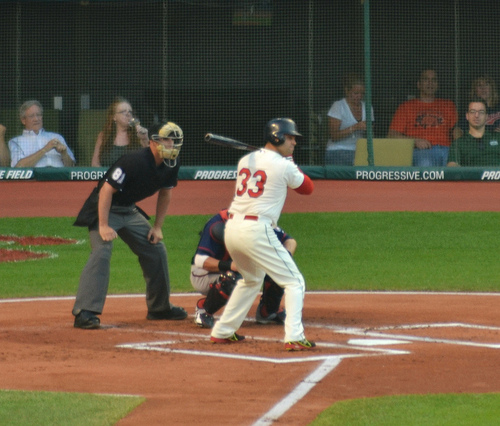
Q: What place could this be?
A: It is a field.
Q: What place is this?
A: It is a field.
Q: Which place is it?
A: It is a field.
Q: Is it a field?
A: Yes, it is a field.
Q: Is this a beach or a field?
A: It is a field.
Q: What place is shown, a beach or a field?
A: It is a field.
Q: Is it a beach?
A: No, it is a field.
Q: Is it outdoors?
A: Yes, it is outdoors.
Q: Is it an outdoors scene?
A: Yes, it is outdoors.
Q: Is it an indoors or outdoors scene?
A: It is outdoors.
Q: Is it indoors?
A: No, it is outdoors.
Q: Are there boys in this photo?
A: No, there are no boys.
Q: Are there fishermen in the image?
A: No, there are no fishermen.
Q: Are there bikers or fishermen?
A: No, there are no fishermen or bikers.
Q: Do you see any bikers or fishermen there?
A: No, there are no fishermen or bikers.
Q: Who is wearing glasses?
A: The man is wearing glasses.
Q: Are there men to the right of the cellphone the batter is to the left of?
A: Yes, there is a man to the right of the cellphone.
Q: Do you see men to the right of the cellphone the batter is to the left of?
A: Yes, there is a man to the right of the cellphone.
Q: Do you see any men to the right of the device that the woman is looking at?
A: Yes, there is a man to the right of the cellphone.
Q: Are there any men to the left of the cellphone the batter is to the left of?
A: No, the man is to the right of the mobile phone.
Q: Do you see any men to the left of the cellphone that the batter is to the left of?
A: No, the man is to the right of the mobile phone.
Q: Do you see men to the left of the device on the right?
A: No, the man is to the right of the mobile phone.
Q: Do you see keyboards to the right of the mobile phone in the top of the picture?
A: No, there is a man to the right of the cellphone.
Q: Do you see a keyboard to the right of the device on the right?
A: No, there is a man to the right of the cellphone.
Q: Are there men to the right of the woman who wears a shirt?
A: Yes, there is a man to the right of the woman.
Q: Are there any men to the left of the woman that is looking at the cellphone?
A: No, the man is to the right of the woman.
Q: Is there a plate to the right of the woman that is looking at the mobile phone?
A: No, there is a man to the right of the woman.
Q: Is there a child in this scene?
A: No, there are no children.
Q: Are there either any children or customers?
A: No, there are no children or customers.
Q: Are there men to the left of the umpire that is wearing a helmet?
A: Yes, there is a man to the left of the umpire.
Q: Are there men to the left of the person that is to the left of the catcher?
A: Yes, there is a man to the left of the umpire.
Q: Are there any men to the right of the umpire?
A: No, the man is to the left of the umpire.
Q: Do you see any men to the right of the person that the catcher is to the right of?
A: No, the man is to the left of the umpire.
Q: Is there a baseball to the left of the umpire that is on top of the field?
A: No, there is a man to the left of the umpire.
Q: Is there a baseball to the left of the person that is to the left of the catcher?
A: No, there is a man to the left of the umpire.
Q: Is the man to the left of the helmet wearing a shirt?
A: Yes, the man is wearing a shirt.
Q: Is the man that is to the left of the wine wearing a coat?
A: No, the man is wearing a shirt.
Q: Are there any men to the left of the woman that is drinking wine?
A: Yes, there is a man to the left of the woman.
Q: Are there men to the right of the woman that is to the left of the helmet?
A: No, the man is to the left of the woman.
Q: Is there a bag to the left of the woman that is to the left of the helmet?
A: No, there is a man to the left of the woman.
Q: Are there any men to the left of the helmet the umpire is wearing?
A: Yes, there is a man to the left of the helmet.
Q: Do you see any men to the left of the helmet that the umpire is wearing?
A: Yes, there is a man to the left of the helmet.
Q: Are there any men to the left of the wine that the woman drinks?
A: Yes, there is a man to the left of the wine.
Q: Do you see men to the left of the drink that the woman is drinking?
A: Yes, there is a man to the left of the wine.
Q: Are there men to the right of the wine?
A: No, the man is to the left of the wine.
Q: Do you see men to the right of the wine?
A: No, the man is to the left of the wine.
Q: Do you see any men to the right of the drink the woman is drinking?
A: No, the man is to the left of the wine.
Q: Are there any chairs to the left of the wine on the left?
A: No, there is a man to the left of the wine.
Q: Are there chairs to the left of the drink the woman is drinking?
A: No, there is a man to the left of the wine.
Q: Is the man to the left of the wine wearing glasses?
A: Yes, the man is wearing glasses.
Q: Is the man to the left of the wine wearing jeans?
A: No, the man is wearing glasses.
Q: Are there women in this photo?
A: Yes, there is a woman.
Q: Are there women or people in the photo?
A: Yes, there is a woman.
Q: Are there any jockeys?
A: No, there are no jockeys.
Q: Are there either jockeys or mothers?
A: No, there are no jockeys or mothers.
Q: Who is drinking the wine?
A: The woman is drinking the wine.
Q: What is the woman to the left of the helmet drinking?
A: The woman is drinking wine.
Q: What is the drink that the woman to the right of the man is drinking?
A: The drink is wine.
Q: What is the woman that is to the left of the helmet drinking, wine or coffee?
A: The woman is drinking wine.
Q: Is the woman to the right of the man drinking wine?
A: Yes, the woman is drinking wine.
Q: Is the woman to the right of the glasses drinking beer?
A: No, the woman is drinking wine.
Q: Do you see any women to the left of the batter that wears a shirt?
A: Yes, there is a woman to the left of the batter.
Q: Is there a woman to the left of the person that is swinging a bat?
A: Yes, there is a woman to the left of the batter.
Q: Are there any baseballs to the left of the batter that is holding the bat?
A: No, there is a woman to the left of the batter.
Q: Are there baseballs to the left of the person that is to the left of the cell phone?
A: No, there is a woman to the left of the batter.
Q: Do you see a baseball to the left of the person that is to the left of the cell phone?
A: No, there is a woman to the left of the batter.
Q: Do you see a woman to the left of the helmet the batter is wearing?
A: Yes, there is a woman to the left of the helmet.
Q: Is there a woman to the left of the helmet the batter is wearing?
A: Yes, there is a woman to the left of the helmet.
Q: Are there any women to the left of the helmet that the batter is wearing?
A: Yes, there is a woman to the left of the helmet.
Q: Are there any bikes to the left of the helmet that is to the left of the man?
A: No, there is a woman to the left of the helmet.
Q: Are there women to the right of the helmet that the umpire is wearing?
A: No, the woman is to the left of the helmet.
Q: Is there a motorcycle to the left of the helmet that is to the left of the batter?
A: No, there is a woman to the left of the helmet.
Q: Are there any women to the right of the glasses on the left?
A: Yes, there is a woman to the right of the glasses.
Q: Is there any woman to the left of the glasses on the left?
A: No, the woman is to the right of the glasses.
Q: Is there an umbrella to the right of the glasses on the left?
A: No, there is a woman to the right of the glasses.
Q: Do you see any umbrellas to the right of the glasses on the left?
A: No, there is a woman to the right of the glasses.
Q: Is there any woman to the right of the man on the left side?
A: Yes, there is a woman to the right of the man.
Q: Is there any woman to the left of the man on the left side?
A: No, the woman is to the right of the man.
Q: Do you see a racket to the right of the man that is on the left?
A: No, there is a woman to the right of the man.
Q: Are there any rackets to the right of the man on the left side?
A: No, there is a woman to the right of the man.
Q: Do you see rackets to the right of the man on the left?
A: No, there is a woman to the right of the man.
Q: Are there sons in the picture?
A: No, there are no sons.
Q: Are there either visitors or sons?
A: No, there are no sons or visitors.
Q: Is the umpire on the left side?
A: Yes, the umpire is on the left of the image.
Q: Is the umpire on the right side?
A: No, the umpire is on the left of the image.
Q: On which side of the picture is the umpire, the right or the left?
A: The umpire is on the left of the image.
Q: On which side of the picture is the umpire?
A: The umpire is on the left of the image.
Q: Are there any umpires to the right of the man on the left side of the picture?
A: Yes, there is an umpire to the right of the man.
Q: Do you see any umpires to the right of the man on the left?
A: Yes, there is an umpire to the right of the man.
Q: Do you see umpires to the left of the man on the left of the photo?
A: No, the umpire is to the right of the man.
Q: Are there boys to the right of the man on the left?
A: No, there is an umpire to the right of the man.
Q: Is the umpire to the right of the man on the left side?
A: Yes, the umpire is to the right of the man.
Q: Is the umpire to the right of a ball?
A: No, the umpire is to the right of the man.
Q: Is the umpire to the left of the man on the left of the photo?
A: No, the umpire is to the right of the man.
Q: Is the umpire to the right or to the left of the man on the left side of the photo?
A: The umpire is to the right of the man.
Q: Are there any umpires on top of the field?
A: Yes, there is an umpire on top of the field.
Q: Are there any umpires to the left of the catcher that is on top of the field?
A: Yes, there is an umpire to the left of the catcher.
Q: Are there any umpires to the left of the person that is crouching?
A: Yes, there is an umpire to the left of the catcher.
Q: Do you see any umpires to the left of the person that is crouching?
A: Yes, there is an umpire to the left of the catcher.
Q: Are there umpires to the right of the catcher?
A: No, the umpire is to the left of the catcher.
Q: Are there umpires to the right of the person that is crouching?
A: No, the umpire is to the left of the catcher.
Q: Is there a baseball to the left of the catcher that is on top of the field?
A: No, there is an umpire to the left of the catcher.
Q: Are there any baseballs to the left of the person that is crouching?
A: No, there is an umpire to the left of the catcher.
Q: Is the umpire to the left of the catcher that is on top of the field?
A: Yes, the umpire is to the left of the catcher.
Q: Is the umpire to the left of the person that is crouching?
A: Yes, the umpire is to the left of the catcher.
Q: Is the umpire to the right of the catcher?
A: No, the umpire is to the left of the catcher.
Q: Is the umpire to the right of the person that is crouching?
A: No, the umpire is to the left of the catcher.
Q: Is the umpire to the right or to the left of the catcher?
A: The umpire is to the left of the catcher.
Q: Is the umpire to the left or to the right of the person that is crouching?
A: The umpire is to the left of the catcher.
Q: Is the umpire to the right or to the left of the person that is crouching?
A: The umpire is to the left of the catcher.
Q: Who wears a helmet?
A: The umpire wears a helmet.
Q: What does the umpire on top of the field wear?
A: The umpire wears a helmet.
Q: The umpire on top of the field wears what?
A: The umpire wears a helmet.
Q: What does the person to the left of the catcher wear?
A: The umpire wears a helmet.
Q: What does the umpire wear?
A: The umpire wears a helmet.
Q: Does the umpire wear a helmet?
A: Yes, the umpire wears a helmet.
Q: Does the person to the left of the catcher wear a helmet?
A: Yes, the umpire wears a helmet.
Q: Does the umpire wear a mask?
A: No, the umpire wears a helmet.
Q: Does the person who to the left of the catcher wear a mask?
A: No, the umpire wears a helmet.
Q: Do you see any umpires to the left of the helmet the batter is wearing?
A: Yes, there is an umpire to the left of the helmet.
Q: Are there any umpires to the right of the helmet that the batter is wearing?
A: No, the umpire is to the left of the helmet.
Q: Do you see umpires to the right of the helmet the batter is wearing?
A: No, the umpire is to the left of the helmet.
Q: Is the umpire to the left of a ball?
A: No, the umpire is to the left of the helmet.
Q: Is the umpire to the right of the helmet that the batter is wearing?
A: No, the umpire is to the left of the helmet.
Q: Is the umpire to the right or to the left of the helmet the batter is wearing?
A: The umpire is to the left of the helmet.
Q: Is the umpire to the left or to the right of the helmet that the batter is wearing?
A: The umpire is to the left of the helmet.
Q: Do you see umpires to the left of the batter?
A: Yes, there is an umpire to the left of the batter.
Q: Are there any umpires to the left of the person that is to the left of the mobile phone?
A: Yes, there is an umpire to the left of the batter.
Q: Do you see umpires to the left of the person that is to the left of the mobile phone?
A: Yes, there is an umpire to the left of the batter.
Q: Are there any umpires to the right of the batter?
A: No, the umpire is to the left of the batter.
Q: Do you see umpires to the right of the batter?
A: No, the umpire is to the left of the batter.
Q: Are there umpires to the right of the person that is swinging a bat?
A: No, the umpire is to the left of the batter.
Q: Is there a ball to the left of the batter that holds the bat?
A: No, there is an umpire to the left of the batter.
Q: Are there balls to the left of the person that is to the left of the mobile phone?
A: No, there is an umpire to the left of the batter.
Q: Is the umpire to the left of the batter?
A: Yes, the umpire is to the left of the batter.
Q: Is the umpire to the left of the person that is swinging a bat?
A: Yes, the umpire is to the left of the batter.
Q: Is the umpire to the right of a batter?
A: No, the umpire is to the left of a batter.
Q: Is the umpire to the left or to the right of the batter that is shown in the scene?
A: The umpire is to the left of the batter.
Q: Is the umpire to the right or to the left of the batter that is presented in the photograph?
A: The umpire is to the left of the batter.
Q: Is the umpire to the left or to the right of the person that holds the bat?
A: The umpire is to the left of the batter.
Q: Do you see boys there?
A: No, there are no boys.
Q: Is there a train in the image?
A: No, there are no trains.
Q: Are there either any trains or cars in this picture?
A: No, there are no trains or cars.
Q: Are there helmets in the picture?
A: Yes, there is a helmet.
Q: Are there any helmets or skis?
A: Yes, there is a helmet.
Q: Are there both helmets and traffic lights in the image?
A: No, there is a helmet but no traffic lights.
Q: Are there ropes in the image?
A: No, there are no ropes.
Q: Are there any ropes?
A: No, there are no ropes.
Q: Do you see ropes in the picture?
A: No, there are no ropes.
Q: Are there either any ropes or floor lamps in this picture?
A: No, there are no ropes or floor lamps.